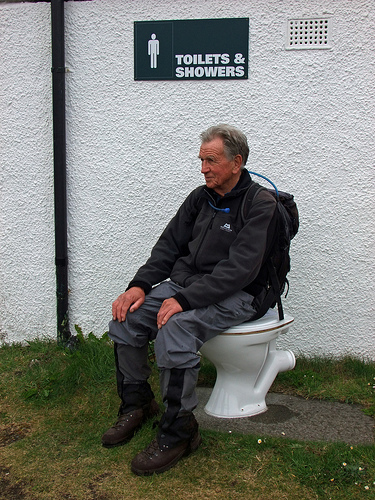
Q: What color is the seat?
A: White.